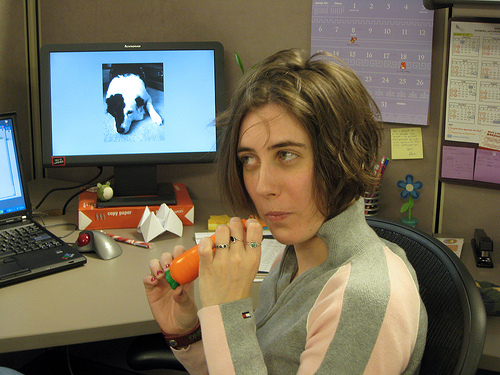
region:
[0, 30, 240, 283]
Two computers on the desk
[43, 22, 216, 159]
Image of the dog on the desktop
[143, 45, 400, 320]
A woman holding a fake carrot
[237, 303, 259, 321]
Tommy Hilfiger logo on the shirt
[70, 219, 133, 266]
Black and silver mouse on the desk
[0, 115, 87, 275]
Laptop computer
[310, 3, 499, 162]
Calendar and planner on the board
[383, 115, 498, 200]
Sticky notes on the wall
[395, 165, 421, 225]
Artificial flower on the desk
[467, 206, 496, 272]
Black stapler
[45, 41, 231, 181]
computer monitor on desk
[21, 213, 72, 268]
laptop on a desk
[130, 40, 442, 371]
woman sitting in a chair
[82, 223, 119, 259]
mouse on a desk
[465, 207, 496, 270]
stapler on a desk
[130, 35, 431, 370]
woman wearing a gray and pink shirt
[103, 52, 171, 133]
dog on a monitor screen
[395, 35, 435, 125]
calendar on a wall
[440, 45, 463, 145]
calendar on a wall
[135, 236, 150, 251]
pen on a desk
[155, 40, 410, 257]
woman is looking to the left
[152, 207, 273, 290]
woman is holding an orange object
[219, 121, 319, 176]
the eyes are open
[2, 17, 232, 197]
the monitor is on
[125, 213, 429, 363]
the sweater is pink and grey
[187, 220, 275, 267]
the woman is wearing rings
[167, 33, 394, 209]
woman`s hair is brown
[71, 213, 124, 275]
the mouse is silver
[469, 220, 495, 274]
a stapler on the desk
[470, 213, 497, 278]
the stapler is black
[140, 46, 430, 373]
young woman with short hair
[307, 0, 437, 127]
purple calendar on wall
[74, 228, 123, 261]
gray mouse on the desk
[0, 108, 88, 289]
black laptop next to mouse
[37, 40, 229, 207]
picture of dog on monitor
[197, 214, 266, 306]
three rings on left hand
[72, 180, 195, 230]
orange box over the monitor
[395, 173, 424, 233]
colored wooden flower on desk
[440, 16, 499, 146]
white calendar on wall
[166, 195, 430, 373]
grey and pink sweater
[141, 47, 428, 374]
A woman in a grey and pink sweater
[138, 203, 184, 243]
A paper fortune telling toy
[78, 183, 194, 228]
A stack of copier paper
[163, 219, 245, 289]
A toy carrot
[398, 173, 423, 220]
A fake blue flower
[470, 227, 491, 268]
A black stapler on a desk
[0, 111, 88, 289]
A black laptop computer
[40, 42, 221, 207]
A computer monitor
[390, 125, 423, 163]
A yellow post it note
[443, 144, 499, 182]
A pair of purple post it notes